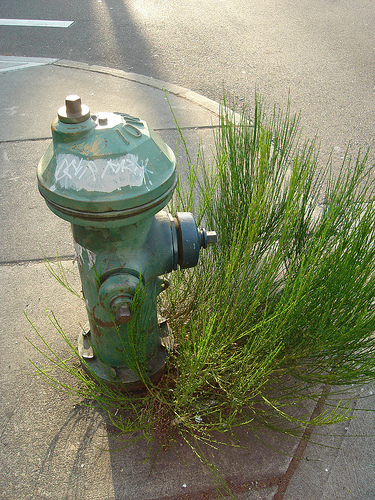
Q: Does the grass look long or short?
A: The grass is long.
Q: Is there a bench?
A: No, there are no benches.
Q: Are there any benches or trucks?
A: No, there are no benches or trucks.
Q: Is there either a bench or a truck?
A: No, there are no benches or trucks.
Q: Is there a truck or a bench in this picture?
A: No, there are no benches or trucks.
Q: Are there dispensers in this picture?
A: No, there are no dispensers.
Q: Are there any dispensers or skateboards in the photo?
A: No, there are no dispensers or skateboards.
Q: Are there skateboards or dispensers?
A: No, there are no dispensers or skateboards.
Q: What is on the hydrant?
A: The graffiti is on the hydrant.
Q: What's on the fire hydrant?
A: The graffiti is on the hydrant.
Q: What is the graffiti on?
A: The graffiti is on the fire hydrant.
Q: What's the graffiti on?
A: The graffiti is on the fire hydrant.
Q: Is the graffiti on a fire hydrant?
A: Yes, the graffiti is on a fire hydrant.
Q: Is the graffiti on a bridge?
A: No, the graffiti is on a fire hydrant.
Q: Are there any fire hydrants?
A: Yes, there is a fire hydrant.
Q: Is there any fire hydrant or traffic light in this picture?
A: Yes, there is a fire hydrant.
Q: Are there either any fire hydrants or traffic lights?
A: Yes, there is a fire hydrant.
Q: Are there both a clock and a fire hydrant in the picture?
A: No, there is a fire hydrant but no clocks.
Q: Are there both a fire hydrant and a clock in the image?
A: No, there is a fire hydrant but no clocks.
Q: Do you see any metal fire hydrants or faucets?
A: Yes, there is a metal fire hydrant.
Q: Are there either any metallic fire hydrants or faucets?
A: Yes, there is a metal fire hydrant.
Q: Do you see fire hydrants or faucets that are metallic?
A: Yes, the fire hydrant is metallic.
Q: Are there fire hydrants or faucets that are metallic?
A: Yes, the fire hydrant is metallic.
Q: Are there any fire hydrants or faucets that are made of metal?
A: Yes, the fire hydrant is made of metal.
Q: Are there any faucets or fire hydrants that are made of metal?
A: Yes, the fire hydrant is made of metal.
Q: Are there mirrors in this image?
A: No, there are no mirrors.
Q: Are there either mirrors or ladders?
A: No, there are no mirrors or ladders.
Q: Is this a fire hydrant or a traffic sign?
A: This is a fire hydrant.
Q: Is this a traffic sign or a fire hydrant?
A: This is a fire hydrant.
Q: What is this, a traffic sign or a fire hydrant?
A: This is a fire hydrant.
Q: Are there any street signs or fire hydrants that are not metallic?
A: No, there is a fire hydrant but it is metallic.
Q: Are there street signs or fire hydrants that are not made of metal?
A: No, there is a fire hydrant but it is made of metal.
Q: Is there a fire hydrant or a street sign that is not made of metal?
A: No, there is a fire hydrant but it is made of metal.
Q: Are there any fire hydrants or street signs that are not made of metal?
A: No, there is a fire hydrant but it is made of metal.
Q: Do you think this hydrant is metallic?
A: Yes, the hydrant is metallic.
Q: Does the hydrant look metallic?
A: Yes, the hydrant is metallic.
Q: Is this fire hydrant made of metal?
A: Yes, the fire hydrant is made of metal.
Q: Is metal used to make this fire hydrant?
A: Yes, the fire hydrant is made of metal.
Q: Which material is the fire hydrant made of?
A: The fire hydrant is made of metal.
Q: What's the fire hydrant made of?
A: The fire hydrant is made of metal.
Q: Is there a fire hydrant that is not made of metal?
A: No, there is a fire hydrant but it is made of metal.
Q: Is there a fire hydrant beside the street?
A: Yes, there is a fire hydrant beside the street.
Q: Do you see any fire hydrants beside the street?
A: Yes, there is a fire hydrant beside the street.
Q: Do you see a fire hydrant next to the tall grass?
A: Yes, there is a fire hydrant next to the grass.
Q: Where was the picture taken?
A: It was taken at the sidewalk.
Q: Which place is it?
A: It is a sidewalk.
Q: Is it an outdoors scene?
A: Yes, it is outdoors.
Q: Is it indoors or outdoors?
A: It is outdoors.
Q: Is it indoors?
A: No, it is outdoors.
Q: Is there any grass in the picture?
A: Yes, there is grass.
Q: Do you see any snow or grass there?
A: Yes, there is grass.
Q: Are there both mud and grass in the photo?
A: No, there is grass but no mud.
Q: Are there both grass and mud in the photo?
A: No, there is grass but no mud.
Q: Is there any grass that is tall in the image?
A: Yes, there is tall grass.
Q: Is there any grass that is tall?
A: Yes, there is grass that is tall.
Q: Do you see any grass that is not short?
A: Yes, there is tall grass.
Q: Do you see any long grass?
A: Yes, there is long grass.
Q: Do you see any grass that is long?
A: Yes, there is grass that is long.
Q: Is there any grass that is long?
A: Yes, there is grass that is long.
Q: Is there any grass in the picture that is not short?
A: Yes, there is long grass.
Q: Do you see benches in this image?
A: No, there are no benches.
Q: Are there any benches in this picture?
A: No, there are no benches.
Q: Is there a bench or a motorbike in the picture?
A: No, there are no benches or motorcycles.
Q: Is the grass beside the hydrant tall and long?
A: Yes, the grass is tall and long.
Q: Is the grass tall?
A: Yes, the grass is tall.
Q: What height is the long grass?
A: The grass is tall.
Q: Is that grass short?
A: No, the grass is tall.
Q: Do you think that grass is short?
A: No, the grass is tall.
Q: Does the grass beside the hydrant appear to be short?
A: No, the grass is tall.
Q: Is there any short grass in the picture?
A: No, there is grass but it is tall.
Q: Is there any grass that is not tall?
A: No, there is grass but it is tall.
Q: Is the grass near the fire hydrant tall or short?
A: The grass is tall.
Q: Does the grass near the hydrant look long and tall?
A: Yes, the grass is long and tall.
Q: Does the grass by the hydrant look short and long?
A: No, the grass is long but tall.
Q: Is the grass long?
A: Yes, the grass is long.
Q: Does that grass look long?
A: Yes, the grass is long.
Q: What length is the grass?
A: The grass is long.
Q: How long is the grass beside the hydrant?
A: The grass is long.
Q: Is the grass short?
A: No, the grass is long.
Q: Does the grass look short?
A: No, the grass is long.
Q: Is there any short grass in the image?
A: No, there is grass but it is long.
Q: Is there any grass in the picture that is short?
A: No, there is grass but it is long.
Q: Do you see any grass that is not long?
A: No, there is grass but it is long.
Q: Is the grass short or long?
A: The grass is long.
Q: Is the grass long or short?
A: The grass is long.